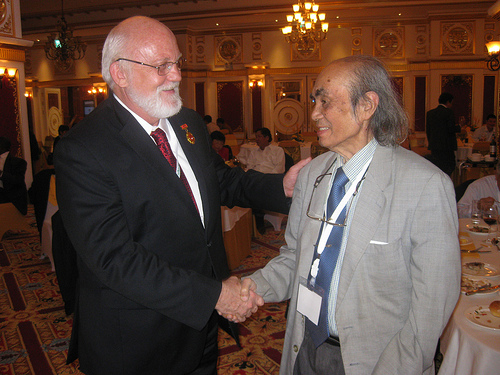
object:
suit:
[54, 88, 292, 373]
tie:
[150, 127, 196, 208]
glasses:
[305, 181, 354, 239]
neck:
[327, 132, 380, 158]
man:
[255, 56, 447, 373]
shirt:
[243, 142, 285, 172]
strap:
[269, 160, 389, 315]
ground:
[391, 200, 403, 220]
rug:
[10, 222, 285, 373]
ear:
[107, 59, 129, 89]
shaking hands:
[207, 270, 268, 327]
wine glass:
[483, 205, 496, 240]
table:
[455, 239, 495, 364]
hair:
[337, 50, 412, 145]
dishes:
[461, 137, 492, 169]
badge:
[171, 115, 213, 164]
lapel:
[164, 104, 227, 166]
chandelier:
[274, 0, 334, 67]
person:
[422, 89, 465, 180]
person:
[227, 125, 289, 232]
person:
[448, 157, 499, 220]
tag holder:
[314, 149, 349, 348]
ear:
[348, 90, 387, 127]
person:
[236, 52, 463, 365]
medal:
[177, 121, 197, 148]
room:
[3, 3, 496, 373]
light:
[310, 0, 318, 11]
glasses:
[105, 47, 243, 85]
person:
[53, 13, 313, 373]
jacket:
[50, 97, 223, 369]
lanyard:
[306, 161, 370, 288]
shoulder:
[379, 138, 441, 181]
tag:
[294, 280, 322, 324]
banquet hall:
[2, 3, 484, 373]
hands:
[201, 259, 269, 330]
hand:
[266, 153, 323, 197]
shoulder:
[295, 143, 344, 185]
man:
[29, 13, 293, 373]